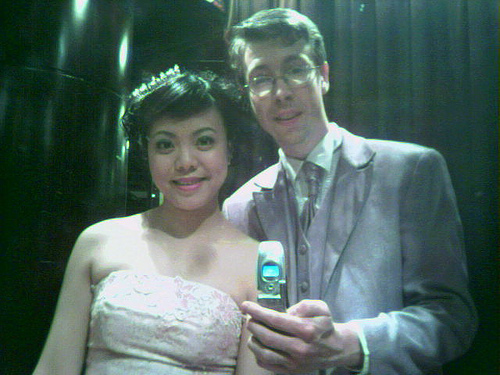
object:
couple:
[32, 7, 480, 375]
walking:
[278, 305, 331, 344]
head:
[118, 63, 251, 211]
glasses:
[241, 65, 322, 97]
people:
[31, 63, 277, 375]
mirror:
[0, 0, 500, 375]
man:
[221, 7, 479, 375]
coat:
[220, 126, 480, 375]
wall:
[0, 0, 137, 210]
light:
[116, 30, 130, 75]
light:
[72, 0, 90, 19]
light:
[116, 101, 130, 162]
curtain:
[229, 0, 500, 280]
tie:
[298, 159, 315, 234]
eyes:
[155, 135, 214, 153]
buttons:
[299, 244, 308, 292]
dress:
[86, 269, 244, 375]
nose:
[175, 152, 199, 170]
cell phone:
[255, 240, 288, 338]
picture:
[0, 0, 500, 375]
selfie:
[32, 7, 480, 375]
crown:
[128, 63, 185, 101]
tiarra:
[124, 57, 204, 127]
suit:
[221, 120, 479, 375]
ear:
[321, 60, 330, 96]